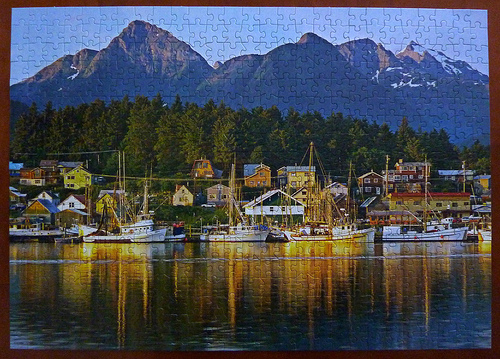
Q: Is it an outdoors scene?
A: Yes, it is outdoors.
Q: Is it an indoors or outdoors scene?
A: It is outdoors.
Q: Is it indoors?
A: No, it is outdoors.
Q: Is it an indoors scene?
A: No, it is outdoors.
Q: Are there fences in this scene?
A: No, there are no fences.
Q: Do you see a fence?
A: No, there are no fences.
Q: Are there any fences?
A: No, there are no fences.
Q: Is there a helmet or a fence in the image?
A: No, there are no fences or helmets.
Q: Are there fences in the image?
A: No, there are no fences.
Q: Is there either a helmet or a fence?
A: No, there are no fences or helmets.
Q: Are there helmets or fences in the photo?
A: No, there are no fences or helmets.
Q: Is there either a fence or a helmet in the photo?
A: No, there are no fences or helmets.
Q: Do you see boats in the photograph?
A: Yes, there is a boat.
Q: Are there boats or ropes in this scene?
A: Yes, there is a boat.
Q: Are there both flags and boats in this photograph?
A: No, there is a boat but no flags.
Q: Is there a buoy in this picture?
A: No, there are no buoys.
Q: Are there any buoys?
A: No, there are no buoys.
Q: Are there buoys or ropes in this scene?
A: No, there are no buoys or ropes.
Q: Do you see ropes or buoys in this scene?
A: No, there are no buoys or ropes.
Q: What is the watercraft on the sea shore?
A: The watercraft is a boat.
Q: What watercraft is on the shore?
A: The watercraft is a boat.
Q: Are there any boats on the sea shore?
A: Yes, there is a boat on the sea shore.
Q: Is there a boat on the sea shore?
A: Yes, there is a boat on the sea shore.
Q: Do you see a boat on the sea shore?
A: Yes, there is a boat on the sea shore.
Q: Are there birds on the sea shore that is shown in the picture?
A: No, there is a boat on the sea shore.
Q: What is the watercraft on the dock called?
A: The watercraft is a boat.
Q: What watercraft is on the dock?
A: The watercraft is a boat.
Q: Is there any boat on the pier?
A: Yes, there is a boat on the pier.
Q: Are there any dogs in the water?
A: No, there is a boat in the water.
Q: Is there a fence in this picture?
A: No, there are no fences.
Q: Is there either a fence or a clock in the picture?
A: No, there are no fences or clocks.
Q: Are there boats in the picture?
A: Yes, there is a boat.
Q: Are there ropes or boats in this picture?
A: Yes, there is a boat.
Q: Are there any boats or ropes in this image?
A: Yes, there is a boat.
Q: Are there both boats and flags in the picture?
A: No, there is a boat but no flags.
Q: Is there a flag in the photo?
A: No, there are no flags.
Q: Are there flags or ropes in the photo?
A: No, there are no flags or ropes.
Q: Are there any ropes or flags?
A: No, there are no flags or ropes.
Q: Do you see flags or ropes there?
A: No, there are no flags or ropes.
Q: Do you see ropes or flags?
A: No, there are no flags or ropes.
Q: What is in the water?
A: The boat is in the water.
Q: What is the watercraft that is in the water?
A: The watercraft is a boat.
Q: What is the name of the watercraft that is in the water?
A: The watercraft is a boat.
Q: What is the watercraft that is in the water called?
A: The watercraft is a boat.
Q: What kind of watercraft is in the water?
A: The watercraft is a boat.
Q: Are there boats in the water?
A: Yes, there is a boat in the water.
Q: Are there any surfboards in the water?
A: No, there is a boat in the water.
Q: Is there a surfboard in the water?
A: No, there is a boat in the water.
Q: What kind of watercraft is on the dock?
A: The watercraft is a boat.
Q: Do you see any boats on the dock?
A: Yes, there is a boat on the dock.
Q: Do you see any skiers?
A: No, there are no skiers.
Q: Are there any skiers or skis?
A: No, there are no skiers or skis.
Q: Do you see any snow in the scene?
A: Yes, there is snow.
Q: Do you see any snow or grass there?
A: Yes, there is snow.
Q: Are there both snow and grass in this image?
A: No, there is snow but no grass.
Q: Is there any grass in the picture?
A: No, there is no grass.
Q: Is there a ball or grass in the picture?
A: No, there are no grass or balls.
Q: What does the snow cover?
A: The snow covers the mountain.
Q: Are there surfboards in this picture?
A: No, there are no surfboards.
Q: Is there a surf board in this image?
A: No, there are no surfboards.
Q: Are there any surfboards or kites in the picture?
A: No, there are no surfboards or kites.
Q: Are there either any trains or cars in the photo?
A: No, there are no cars or trains.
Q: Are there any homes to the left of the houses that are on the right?
A: Yes, there are homes to the left of the houses.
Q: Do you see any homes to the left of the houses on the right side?
A: Yes, there are homes to the left of the houses.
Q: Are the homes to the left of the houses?
A: Yes, the homes are to the left of the houses.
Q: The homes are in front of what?
A: The homes are in front of the trees.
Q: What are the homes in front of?
A: The homes are in front of the trees.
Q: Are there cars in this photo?
A: No, there are no cars.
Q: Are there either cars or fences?
A: No, there are no cars or fences.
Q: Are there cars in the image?
A: No, there are no cars.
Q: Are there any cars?
A: No, there are no cars.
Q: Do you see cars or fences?
A: No, there are no cars or fences.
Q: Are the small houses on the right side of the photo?
A: Yes, the houses are on the right of the image.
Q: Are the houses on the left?
A: No, the houses are on the right of the image.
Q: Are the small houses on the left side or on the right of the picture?
A: The houses are on the right of the image.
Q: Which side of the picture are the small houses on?
A: The houses are on the right of the image.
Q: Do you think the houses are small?
A: Yes, the houses are small.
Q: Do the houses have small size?
A: Yes, the houses are small.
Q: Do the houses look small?
A: Yes, the houses are small.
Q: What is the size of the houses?
A: The houses are small.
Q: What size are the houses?
A: The houses are small.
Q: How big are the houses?
A: The houses are small.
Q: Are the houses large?
A: No, the houses are small.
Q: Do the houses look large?
A: No, the houses are small.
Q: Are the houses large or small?
A: The houses are small.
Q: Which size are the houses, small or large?
A: The houses are small.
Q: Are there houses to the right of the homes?
A: Yes, there are houses to the right of the homes.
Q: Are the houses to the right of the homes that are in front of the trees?
A: Yes, the houses are to the right of the homes.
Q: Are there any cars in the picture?
A: No, there are no cars.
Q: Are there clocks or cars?
A: No, there are no cars or clocks.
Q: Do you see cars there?
A: No, there are no cars.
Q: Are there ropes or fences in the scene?
A: No, there are no fences or ropes.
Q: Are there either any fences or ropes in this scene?
A: No, there are no fences or ropes.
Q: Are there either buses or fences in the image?
A: No, there are no fences or buses.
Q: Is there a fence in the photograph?
A: No, there are no fences.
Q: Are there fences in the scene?
A: No, there are no fences.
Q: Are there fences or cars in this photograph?
A: No, there are no fences or cars.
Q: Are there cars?
A: No, there are no cars.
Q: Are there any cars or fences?
A: No, there are no cars or fences.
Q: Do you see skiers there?
A: No, there are no skiers.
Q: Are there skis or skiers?
A: No, there are no skiers or skis.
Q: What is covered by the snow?
A: The mountain is covered by the snow.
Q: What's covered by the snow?
A: The mountain is covered by the snow.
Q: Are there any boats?
A: Yes, there is a boat.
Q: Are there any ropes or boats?
A: Yes, there is a boat.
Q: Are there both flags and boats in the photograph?
A: No, there is a boat but no flags.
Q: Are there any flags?
A: No, there are no flags.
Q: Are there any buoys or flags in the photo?
A: No, there are no flags or buoys.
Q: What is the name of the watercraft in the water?
A: The watercraft is a boat.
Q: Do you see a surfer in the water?
A: No, there is a boat in the water.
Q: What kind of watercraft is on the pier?
A: The watercraft is a boat.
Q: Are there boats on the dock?
A: Yes, there is a boat on the dock.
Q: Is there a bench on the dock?
A: No, there is a boat on the dock.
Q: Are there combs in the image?
A: No, there are no combs.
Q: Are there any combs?
A: No, there are no combs.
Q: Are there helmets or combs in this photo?
A: No, there are no combs or helmets.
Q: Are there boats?
A: Yes, there is a boat.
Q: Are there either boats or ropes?
A: Yes, there is a boat.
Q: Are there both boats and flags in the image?
A: No, there is a boat but no flags.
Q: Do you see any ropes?
A: No, there are no ropes.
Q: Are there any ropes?
A: No, there are no ropes.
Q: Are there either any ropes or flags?
A: No, there are no ropes or flags.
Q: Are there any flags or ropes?
A: No, there are no ropes or flags.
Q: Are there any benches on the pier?
A: No, there is a boat on the pier.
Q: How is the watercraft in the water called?
A: The watercraft is a boat.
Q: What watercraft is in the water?
A: The watercraft is a boat.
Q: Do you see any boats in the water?
A: Yes, there is a boat in the water.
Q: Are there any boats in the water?
A: Yes, there is a boat in the water.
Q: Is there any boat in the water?
A: Yes, there is a boat in the water.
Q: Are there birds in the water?
A: No, there is a boat in the water.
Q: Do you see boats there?
A: Yes, there is a boat.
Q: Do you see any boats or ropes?
A: Yes, there is a boat.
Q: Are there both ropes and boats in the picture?
A: No, there is a boat but no ropes.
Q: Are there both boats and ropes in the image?
A: No, there is a boat but no ropes.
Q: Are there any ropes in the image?
A: No, there are no ropes.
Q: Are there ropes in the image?
A: No, there are no ropes.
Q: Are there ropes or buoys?
A: No, there are no ropes or buoys.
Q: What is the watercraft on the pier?
A: The watercraft is a boat.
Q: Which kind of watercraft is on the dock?
A: The watercraft is a boat.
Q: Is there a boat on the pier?
A: Yes, there is a boat on the pier.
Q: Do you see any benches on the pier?
A: No, there is a boat on the pier.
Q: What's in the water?
A: The boat is in the water.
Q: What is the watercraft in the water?
A: The watercraft is a boat.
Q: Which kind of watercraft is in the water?
A: The watercraft is a boat.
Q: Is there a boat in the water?
A: Yes, there is a boat in the water.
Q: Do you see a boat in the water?
A: Yes, there is a boat in the water.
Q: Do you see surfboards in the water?
A: No, there is a boat in the water.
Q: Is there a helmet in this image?
A: No, there are no helmets.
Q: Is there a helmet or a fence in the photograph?
A: No, there are no helmets or fences.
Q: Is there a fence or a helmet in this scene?
A: No, there are no helmets or fences.